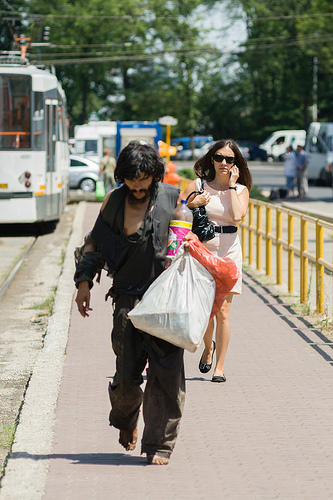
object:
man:
[73, 142, 200, 459]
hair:
[114, 141, 165, 187]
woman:
[182, 135, 254, 387]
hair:
[192, 134, 252, 191]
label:
[168, 219, 192, 254]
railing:
[240, 191, 330, 326]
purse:
[185, 188, 214, 242]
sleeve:
[73, 183, 120, 287]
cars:
[173, 118, 308, 158]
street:
[162, 144, 299, 184]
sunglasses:
[210, 151, 237, 164]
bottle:
[161, 196, 194, 264]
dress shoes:
[211, 370, 226, 383]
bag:
[124, 241, 220, 355]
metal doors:
[42, 95, 61, 221]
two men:
[281, 142, 310, 193]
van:
[259, 124, 307, 163]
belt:
[210, 222, 239, 238]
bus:
[1, 62, 71, 232]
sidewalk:
[0, 201, 329, 499]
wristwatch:
[229, 184, 238, 191]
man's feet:
[145, 444, 171, 469]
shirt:
[70, 184, 191, 309]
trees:
[99, 1, 146, 130]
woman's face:
[214, 146, 235, 177]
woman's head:
[193, 138, 253, 191]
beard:
[125, 185, 149, 203]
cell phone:
[227, 163, 237, 179]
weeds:
[25, 279, 58, 318]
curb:
[0, 197, 90, 499]